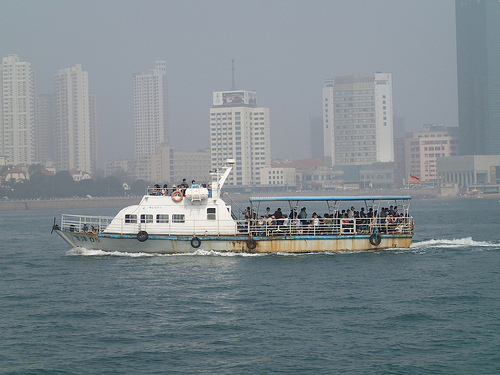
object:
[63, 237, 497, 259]
wave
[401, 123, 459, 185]
building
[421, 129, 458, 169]
wall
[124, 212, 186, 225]
windows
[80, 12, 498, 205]
pillars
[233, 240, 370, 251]
rust spots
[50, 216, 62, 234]
tip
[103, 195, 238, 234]
cabin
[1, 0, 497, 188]
buildings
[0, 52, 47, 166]
building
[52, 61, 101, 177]
building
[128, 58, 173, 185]
building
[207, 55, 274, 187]
building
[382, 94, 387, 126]
window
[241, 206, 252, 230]
person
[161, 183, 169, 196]
person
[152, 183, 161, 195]
person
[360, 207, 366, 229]
person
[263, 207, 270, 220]
person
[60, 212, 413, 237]
railings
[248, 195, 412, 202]
roof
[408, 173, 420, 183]
flag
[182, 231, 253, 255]
object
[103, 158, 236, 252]
white boat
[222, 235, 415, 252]
side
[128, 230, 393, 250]
rings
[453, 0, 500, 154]
black building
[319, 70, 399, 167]
building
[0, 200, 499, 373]
water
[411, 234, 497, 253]
wake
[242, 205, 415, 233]
people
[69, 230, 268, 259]
floats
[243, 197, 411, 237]
shelter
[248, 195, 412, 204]
blue top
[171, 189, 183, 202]
float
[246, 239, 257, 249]
tire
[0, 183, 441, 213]
shoreline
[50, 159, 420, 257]
boat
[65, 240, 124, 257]
waves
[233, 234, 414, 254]
bottom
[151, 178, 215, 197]
people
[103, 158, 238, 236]
boat's cabin